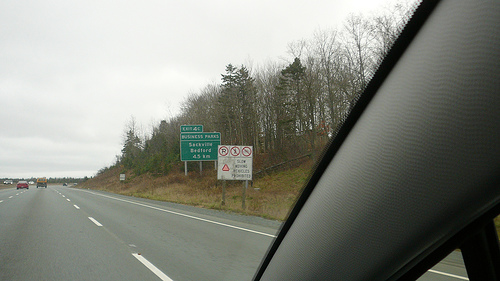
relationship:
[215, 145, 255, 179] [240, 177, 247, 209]
street sign on a post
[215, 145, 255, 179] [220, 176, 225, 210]
street sign on a post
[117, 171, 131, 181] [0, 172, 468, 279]
sign on highway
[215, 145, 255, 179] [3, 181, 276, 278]
street sign on highway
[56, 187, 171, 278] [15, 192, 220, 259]
lines in road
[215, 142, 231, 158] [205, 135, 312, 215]
no parking on sign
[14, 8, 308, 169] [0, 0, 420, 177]
clouds in sky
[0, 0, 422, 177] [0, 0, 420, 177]
clouds in sky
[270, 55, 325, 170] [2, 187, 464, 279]
tree on side of road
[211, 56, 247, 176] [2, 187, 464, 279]
tree on side of road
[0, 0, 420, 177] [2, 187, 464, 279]
sky above road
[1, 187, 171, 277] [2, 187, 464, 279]
lines on road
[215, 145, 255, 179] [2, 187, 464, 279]
street sign near road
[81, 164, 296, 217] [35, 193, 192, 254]
grasses next to road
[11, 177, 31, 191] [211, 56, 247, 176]
vehicle driving near tree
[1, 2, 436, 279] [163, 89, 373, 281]
windshield of a vehicle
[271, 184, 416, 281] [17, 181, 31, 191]
part of inside of vehicle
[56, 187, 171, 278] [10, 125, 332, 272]
lines on road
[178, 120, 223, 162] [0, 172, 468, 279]
sign on side of highway